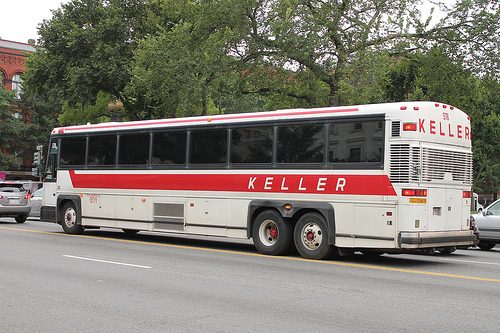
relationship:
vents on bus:
[394, 143, 494, 180] [128, 99, 480, 266]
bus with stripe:
[41, 100, 480, 260] [65, 104, 360, 139]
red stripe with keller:
[65, 163, 403, 201] [419, 118, 471, 139]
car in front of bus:
[0, 180, 32, 222] [41, 100, 480, 260]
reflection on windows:
[230, 115, 385, 164] [328, 115, 385, 164]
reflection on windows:
[230, 115, 385, 164] [278, 121, 324, 166]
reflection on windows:
[230, 115, 385, 164] [230, 122, 273, 164]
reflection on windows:
[230, 115, 385, 164] [187, 122, 227, 166]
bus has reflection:
[41, 100, 480, 260] [230, 115, 385, 164]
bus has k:
[41, 100, 480, 260] [419, 118, 426, 133]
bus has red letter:
[41, 100, 480, 260] [427, 117, 438, 134]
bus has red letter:
[41, 100, 480, 260] [435, 118, 447, 135]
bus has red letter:
[41, 100, 480, 260] [445, 116, 455, 138]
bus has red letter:
[41, 100, 480, 260] [453, 122, 464, 139]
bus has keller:
[41, 100, 480, 260] [414, 115, 470, 141]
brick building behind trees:
[4, 38, 43, 163] [23, 1, 260, 113]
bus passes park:
[41, 100, 480, 260] [0, 0, 499, 195]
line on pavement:
[64, 254, 152, 270] [0, 207, 498, 331]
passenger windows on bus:
[56, 114, 385, 168] [41, 100, 480, 260]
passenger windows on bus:
[56, 114, 385, 168] [18, 125, 483, 265]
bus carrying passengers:
[41, 100, 480, 260] [63, 144, 383, 164]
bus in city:
[41, 100, 480, 260] [4, 10, 477, 331]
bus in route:
[41, 100, 480, 260] [4, 220, 483, 308]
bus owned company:
[41, 100, 480, 260] [247, 172, 349, 193]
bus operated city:
[43, 96, 384, 330] [4, 10, 477, 331]